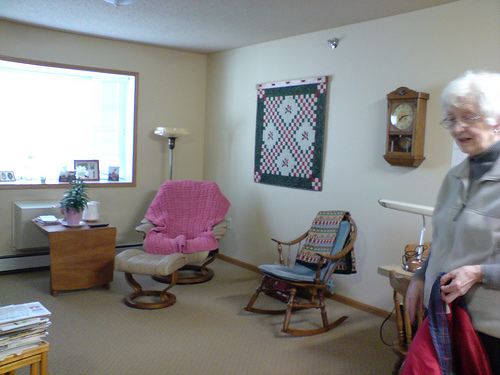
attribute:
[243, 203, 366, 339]
chair — blue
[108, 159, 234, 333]
chair — white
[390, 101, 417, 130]
clock — wooden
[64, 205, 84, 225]
vase — white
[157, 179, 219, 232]
cloth — pink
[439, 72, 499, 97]
hair — grey, white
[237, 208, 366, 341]
rocking chair — brown, wooden, swivel, blue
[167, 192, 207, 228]
blanket — pink, knit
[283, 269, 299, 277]
cushion — blue, beige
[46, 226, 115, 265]
table — light brown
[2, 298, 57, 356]
papers — white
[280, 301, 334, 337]
chair leg — brown, wooden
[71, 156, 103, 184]
picture — framed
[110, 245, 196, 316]
ottoman — cloth covered